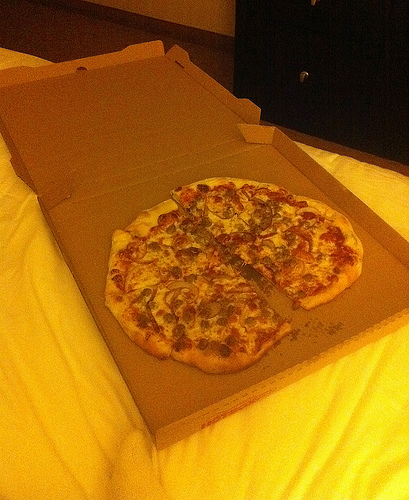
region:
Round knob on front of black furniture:
[298, 67, 312, 83]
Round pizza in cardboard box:
[100, 160, 356, 380]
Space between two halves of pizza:
[226, 256, 308, 334]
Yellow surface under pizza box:
[1, 399, 406, 498]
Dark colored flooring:
[0, 12, 237, 82]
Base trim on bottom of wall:
[132, 12, 216, 41]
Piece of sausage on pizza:
[165, 224, 177, 235]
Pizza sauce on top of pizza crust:
[343, 241, 358, 273]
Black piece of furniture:
[232, 0, 406, 162]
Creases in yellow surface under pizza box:
[289, 403, 389, 490]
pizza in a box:
[89, 164, 367, 389]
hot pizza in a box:
[72, 178, 384, 415]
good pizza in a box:
[65, 169, 381, 426]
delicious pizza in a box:
[80, 180, 383, 419]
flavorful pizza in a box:
[73, 167, 377, 416]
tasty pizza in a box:
[79, 174, 378, 439]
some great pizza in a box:
[58, 164, 379, 427]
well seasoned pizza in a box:
[62, 160, 378, 408]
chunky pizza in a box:
[78, 164, 373, 404]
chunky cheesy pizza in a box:
[71, 161, 375, 379]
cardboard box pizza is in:
[4, 34, 408, 446]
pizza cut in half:
[95, 177, 375, 405]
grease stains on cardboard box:
[269, 305, 337, 351]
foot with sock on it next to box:
[100, 426, 178, 486]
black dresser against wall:
[233, 1, 408, 151]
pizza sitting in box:
[87, 160, 361, 362]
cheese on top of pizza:
[132, 192, 334, 345]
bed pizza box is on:
[4, 52, 398, 498]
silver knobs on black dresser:
[293, 1, 323, 85]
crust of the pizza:
[99, 168, 371, 369]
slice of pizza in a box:
[111, 198, 229, 259]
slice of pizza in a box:
[98, 229, 223, 299]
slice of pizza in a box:
[97, 257, 235, 364]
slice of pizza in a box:
[167, 268, 291, 381]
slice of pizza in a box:
[224, 239, 369, 310]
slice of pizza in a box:
[230, 195, 364, 267]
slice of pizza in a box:
[170, 172, 272, 254]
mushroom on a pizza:
[200, 295, 225, 320]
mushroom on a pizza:
[166, 277, 201, 313]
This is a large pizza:
[89, 175, 374, 466]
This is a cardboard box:
[38, 333, 231, 460]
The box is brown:
[119, 386, 273, 441]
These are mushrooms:
[158, 261, 208, 302]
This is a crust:
[168, 318, 279, 400]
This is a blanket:
[240, 477, 278, 493]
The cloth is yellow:
[19, 423, 124, 480]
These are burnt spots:
[121, 299, 177, 355]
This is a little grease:
[294, 303, 385, 370]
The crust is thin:
[170, 334, 219, 360]